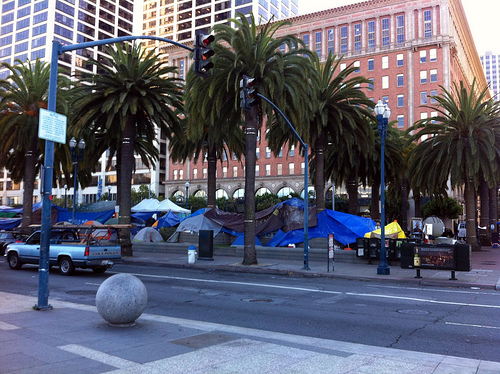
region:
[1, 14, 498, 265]
A Bunch Of Palm Trees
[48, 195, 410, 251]
Group Of Tents in a row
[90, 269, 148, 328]
Big Concrete Ball on Sidewalk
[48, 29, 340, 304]
Traffic Lights Hanging Over The Street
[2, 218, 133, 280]
Light Blue Pick Up Truck With Ladder On Top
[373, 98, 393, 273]
Old-Fashion Two Light Streetlight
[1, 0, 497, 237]
Tall office buildings in the city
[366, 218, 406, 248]
Bright Yellow Tarp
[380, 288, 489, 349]
Large Crack In The Road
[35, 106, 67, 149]
Green And White Sign On Traffic Pole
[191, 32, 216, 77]
an electric traffic sign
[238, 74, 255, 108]
an electric traffic sign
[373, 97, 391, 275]
a blue street light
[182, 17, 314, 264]
a large green palm tree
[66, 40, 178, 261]
a large green palm tree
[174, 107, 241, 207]
a large green palm tree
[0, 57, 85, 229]
a large green palm tree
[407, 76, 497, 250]
a large green palm tree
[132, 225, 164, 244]
a light blue pop up tent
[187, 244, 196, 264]
a white and blue fire hydrant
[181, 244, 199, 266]
Blue and white fire hydrant.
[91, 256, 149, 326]
Grey large ball on sidewalk.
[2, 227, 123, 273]
Light blue trunk in street.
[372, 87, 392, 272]
Street lights with two globes near ad.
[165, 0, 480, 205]
Red and grey building.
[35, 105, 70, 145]
White sign with dark letters.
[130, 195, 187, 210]
Two white tents surrounded by others.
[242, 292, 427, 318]
Two brown manholes in street.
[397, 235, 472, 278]
Display showing ad with green bottle.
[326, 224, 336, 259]
Red and white sign display.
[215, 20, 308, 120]
top of a palm tree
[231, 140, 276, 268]
long brown branch of tree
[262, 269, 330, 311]
white line on the ground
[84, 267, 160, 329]
round object on cement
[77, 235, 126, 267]
back of a truck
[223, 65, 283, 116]
light above the street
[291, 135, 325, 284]
pole on the ground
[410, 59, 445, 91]
windows on the building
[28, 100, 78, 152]
sign on the pole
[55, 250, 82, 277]
back tire of truck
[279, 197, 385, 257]
THE TARP IS BLUE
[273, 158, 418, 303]
THE TARP IS BLUE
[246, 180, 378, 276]
THE TARP IS BLUE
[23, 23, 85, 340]
the pole is blue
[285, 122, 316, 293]
the pole is blue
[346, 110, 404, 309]
the pole is blue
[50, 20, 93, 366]
the pole is blue